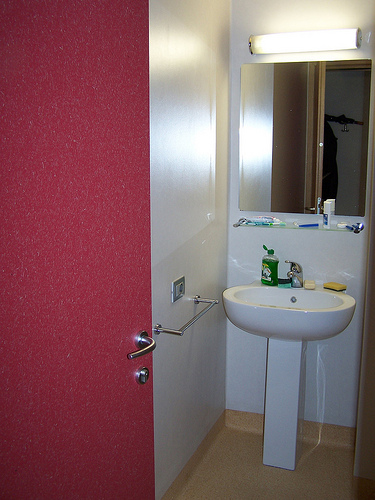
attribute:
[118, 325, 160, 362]
handle — metal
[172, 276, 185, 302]
lightswitch — metal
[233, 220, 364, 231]
shelf — glass, floating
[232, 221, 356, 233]
shelf — glass, floating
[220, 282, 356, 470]
pedestal sink — white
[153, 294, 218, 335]
towel bar — stainless steel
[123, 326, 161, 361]
handle — stainless steel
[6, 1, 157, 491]
door — red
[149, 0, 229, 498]
wall — bright white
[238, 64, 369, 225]
mirror — large, reflective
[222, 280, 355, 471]
sink — small, white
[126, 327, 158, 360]
knob — stainless steel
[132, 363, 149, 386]
lock — stainless steel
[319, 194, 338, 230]
item — personal care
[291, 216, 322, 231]
item — personal care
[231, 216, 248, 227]
item — personal care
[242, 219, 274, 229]
item — personal care